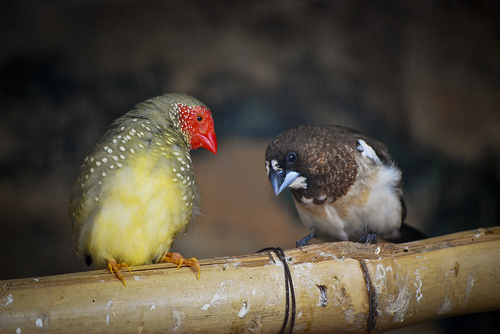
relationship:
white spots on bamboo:
[0, 227, 487, 331] [9, 238, 494, 321]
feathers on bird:
[322, 184, 400, 236] [245, 112, 422, 258]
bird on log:
[262, 113, 432, 263] [5, 202, 484, 318]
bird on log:
[44, 64, 226, 271] [5, 202, 484, 318]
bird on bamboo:
[262, 113, 432, 263] [4, 220, 484, 329]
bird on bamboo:
[73, 91, 226, 271] [4, 220, 484, 329]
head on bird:
[263, 122, 330, 193] [258, 117, 433, 248]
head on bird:
[174, 94, 220, 156] [58, 77, 227, 300]